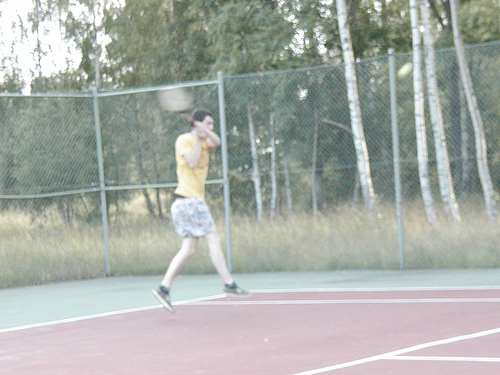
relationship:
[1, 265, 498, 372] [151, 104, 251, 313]
court under man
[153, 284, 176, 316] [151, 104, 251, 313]
shoe on man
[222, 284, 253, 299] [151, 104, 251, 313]
shoe on man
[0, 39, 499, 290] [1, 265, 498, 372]
fence on court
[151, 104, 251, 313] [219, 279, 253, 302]
man has right-foot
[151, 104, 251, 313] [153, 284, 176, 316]
man has a left-foot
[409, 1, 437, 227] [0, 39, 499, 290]
trunk behind fence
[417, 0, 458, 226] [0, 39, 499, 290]
trunk behind fence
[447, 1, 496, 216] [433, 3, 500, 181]
trunk of tree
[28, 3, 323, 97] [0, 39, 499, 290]
tree behind fence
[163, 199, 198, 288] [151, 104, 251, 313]
leg of man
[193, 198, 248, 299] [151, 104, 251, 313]
leg of man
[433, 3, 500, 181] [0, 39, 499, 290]
tree above fence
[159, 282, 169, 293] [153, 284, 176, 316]
sock on shoe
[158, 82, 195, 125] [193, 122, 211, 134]
racquet in hand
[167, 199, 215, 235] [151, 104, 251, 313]
shorts on man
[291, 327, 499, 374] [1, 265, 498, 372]
lines on court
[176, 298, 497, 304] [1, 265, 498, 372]
lines on court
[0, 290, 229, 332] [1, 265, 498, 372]
lines on court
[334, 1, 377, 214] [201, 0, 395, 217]
trunk of a tree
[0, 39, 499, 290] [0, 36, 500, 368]
trees behind tennis court